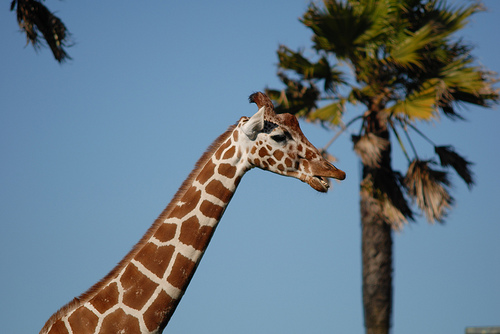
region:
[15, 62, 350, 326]
this is a giraffe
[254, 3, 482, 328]
this is a tree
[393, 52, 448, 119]
this is a branch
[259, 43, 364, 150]
this is a branch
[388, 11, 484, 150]
this is a branch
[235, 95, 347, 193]
giraffe with mouth open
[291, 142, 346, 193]
narrow upper lip over rounder lower lip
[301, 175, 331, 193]
a few white teeth showing on lower lip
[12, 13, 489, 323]
clear blue sky behind giraffe and tree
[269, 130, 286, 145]
dark oval-shaped eye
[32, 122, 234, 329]
short brown mane along neck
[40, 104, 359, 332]
head and neck of giraffe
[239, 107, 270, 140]
white ear of the giraffe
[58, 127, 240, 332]
brown spots on the giraffe's neck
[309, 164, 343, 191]
open mouth of the giraffe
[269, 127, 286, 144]
eye of the giraffe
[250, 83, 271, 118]
horns on the giraffe's head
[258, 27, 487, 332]
palm tree on the right side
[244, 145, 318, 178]
brown spots on the giraffe's face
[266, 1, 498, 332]
green leaves of palm tree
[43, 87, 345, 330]
side of giraffe head and neck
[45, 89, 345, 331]
giraffe with open mouth on face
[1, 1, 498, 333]
sky is bright blue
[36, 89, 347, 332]
giraffe has horns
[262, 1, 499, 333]
palm tree has palm fronds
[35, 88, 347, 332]
giraffe's mouth is open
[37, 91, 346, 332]
giraffe is brown and white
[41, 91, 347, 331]
giraffe has white ears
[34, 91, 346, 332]
giraffe has a dark eye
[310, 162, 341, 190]
mouth of giraffe is open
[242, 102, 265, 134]
ear on head of giraffe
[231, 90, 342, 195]
head belongs to giraffe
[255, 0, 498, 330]
tree behind giraffe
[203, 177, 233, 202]
spot on giraffe neck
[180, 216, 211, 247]
spot on giraffe neck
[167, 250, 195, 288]
spot on giraffe neck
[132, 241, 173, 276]
spot on giraffe neck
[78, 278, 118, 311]
spot on giraffe neck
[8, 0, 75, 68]
leaves hang over giraffe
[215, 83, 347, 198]
the head of a giraffe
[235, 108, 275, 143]
the ear of a giraffe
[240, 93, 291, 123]
the horn of a giraffe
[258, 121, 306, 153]
the eyes of a giraffe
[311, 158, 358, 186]
the top lip of a giraffe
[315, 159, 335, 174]
the nostril of a giraffe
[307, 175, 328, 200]
the bottom lip of a giraffe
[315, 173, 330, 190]
the teeth of a giraffe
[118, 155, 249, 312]
the neck of a giraffe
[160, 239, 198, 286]
the spots of a giraffe